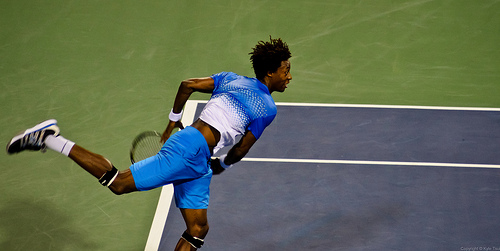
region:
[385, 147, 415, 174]
white line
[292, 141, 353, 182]
white line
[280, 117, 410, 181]
white line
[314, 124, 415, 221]
white line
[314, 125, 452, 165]
white line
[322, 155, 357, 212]
white line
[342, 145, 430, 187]
white line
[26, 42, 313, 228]
Black tennis player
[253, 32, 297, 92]
Dark brown hair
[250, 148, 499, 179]
White line of tennis court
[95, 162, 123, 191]
Black leg band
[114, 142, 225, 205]
Blue shorts on player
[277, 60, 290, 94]
Player's face is brown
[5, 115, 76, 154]
Black and white tennis shoes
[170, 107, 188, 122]
White wrist band on left arm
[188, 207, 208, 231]
Leg muscle is bulging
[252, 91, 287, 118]
Man's right shoulder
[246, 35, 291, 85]
black natural hair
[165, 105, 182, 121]
a white wristband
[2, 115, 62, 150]
a man's tennis shoe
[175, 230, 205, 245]
a black and white leg band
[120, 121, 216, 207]
a man's blue shorts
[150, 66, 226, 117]
the arm of a man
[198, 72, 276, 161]
a man's short sleeve blue and white shirt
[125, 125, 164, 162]
part of a tennis racket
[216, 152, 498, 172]
a long white line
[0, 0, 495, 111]
part of a tennis court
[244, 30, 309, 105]
a man with dark hair.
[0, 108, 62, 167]
A shoe on a right foot.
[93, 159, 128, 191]
a brace on a right knee.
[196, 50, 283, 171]
a blue and white shirt.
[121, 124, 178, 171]
a tennis racket in a tennis player's hand.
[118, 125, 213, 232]
a pair of baby blue shorts.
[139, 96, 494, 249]
a blue and white tennis court.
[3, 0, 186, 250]
a section of a green tennis court.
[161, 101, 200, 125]
a brace on a left arm.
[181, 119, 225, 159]
the mid section of a tennis player.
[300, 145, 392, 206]
white line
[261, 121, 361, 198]
white line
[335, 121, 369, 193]
white line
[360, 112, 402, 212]
white line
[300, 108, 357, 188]
white line